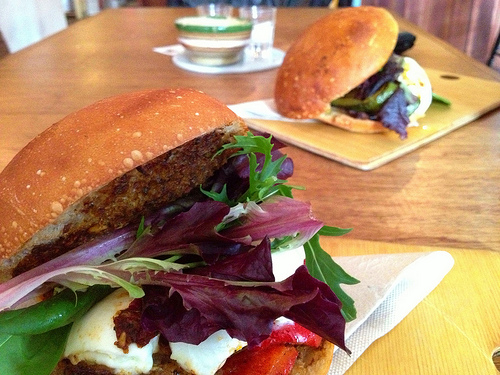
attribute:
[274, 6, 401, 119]
bun — brown, large, oversized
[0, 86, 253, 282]
bun — brown, large, oversized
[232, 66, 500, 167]
plate — white, wooden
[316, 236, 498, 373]
plate — wooden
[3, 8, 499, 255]
table — large, wooden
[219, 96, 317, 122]
napkin — white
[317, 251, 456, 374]
napkin — white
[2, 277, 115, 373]
lettuce — green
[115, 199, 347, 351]
lettuce — purple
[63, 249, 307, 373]
cheese — gooey, american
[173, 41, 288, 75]
plate — circular, white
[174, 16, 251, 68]
bowl — white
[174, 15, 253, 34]
trim — green